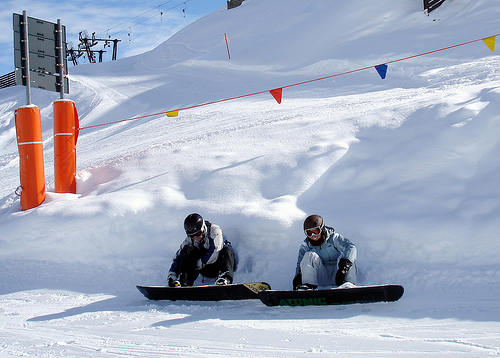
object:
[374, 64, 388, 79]
blue pennant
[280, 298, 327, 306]
lettering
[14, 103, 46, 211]
object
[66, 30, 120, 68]
ski lift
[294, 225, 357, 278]
jacket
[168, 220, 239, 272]
jacket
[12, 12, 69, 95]
sign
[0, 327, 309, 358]
tracks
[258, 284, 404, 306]
snowboard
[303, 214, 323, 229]
helmet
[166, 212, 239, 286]
helmet man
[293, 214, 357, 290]
helmet man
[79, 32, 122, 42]
metal support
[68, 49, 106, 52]
metal support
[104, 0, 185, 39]
wire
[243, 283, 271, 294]
yellow front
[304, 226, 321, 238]
eyewear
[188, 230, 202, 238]
eyewear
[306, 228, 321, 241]
face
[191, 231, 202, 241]
face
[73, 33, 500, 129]
rope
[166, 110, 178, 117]
flag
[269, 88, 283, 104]
flag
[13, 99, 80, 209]
supports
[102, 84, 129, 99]
tracks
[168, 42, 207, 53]
tracks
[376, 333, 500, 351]
tracks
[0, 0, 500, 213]
hill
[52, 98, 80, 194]
object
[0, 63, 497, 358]
ground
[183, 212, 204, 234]
helmet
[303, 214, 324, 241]
head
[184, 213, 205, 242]
head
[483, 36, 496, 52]
flag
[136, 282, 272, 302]
snowboard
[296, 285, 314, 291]
foot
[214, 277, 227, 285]
foot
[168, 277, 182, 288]
foot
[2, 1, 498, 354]
snow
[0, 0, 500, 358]
ski area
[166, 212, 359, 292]
couple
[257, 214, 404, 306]
snowboarding gear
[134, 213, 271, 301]
snowboarding gear